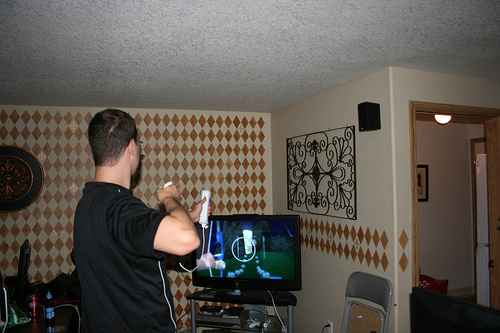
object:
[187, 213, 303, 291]
television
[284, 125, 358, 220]
decoration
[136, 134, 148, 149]
glasses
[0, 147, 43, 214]
black fence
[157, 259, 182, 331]
stripe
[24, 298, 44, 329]
can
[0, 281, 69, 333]
table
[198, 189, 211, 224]
controller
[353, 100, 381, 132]
speaker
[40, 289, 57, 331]
bottle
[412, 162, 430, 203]
picture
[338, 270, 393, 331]
chair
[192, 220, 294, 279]
video game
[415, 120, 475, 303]
wall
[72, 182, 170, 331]
shirt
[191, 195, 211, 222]
hand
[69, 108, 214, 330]
man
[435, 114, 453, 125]
fixture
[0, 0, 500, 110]
ceiling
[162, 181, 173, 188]
wii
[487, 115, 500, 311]
wooden sill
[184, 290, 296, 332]
stand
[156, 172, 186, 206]
remote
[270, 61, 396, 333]
wall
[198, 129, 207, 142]
triangles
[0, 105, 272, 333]
wall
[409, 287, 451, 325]
container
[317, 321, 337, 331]
cord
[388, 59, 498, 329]
doorway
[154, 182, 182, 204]
hand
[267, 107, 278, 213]
corner